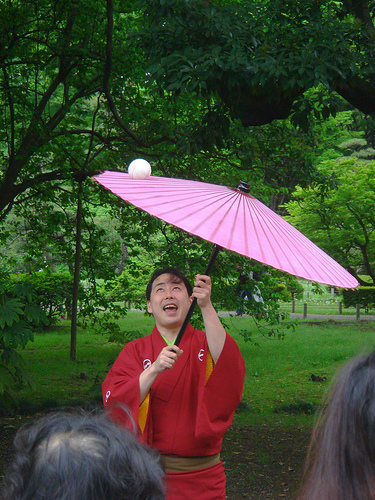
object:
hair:
[0, 400, 167, 500]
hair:
[145, 266, 193, 300]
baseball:
[128, 158, 152, 180]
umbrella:
[92, 168, 361, 292]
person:
[101, 262, 247, 498]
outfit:
[101, 324, 246, 497]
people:
[234, 255, 263, 318]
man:
[0, 410, 165, 497]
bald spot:
[28, 428, 99, 459]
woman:
[298, 348, 374, 499]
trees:
[1, 1, 373, 292]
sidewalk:
[52, 295, 373, 325]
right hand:
[157, 342, 184, 372]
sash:
[140, 451, 222, 474]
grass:
[22, 311, 366, 421]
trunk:
[69, 186, 83, 360]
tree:
[28, 96, 154, 358]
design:
[198, 348, 205, 362]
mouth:
[162, 300, 178, 316]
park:
[6, 2, 368, 497]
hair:
[295, 349, 374, 498]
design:
[141, 358, 152, 369]